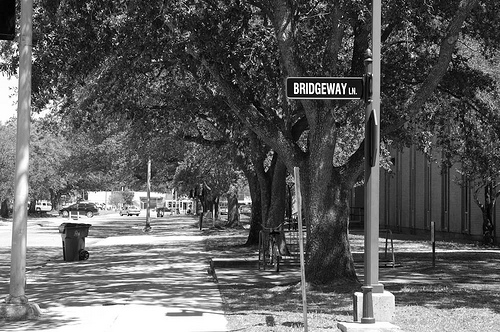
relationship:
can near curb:
[59, 221, 90, 261] [0, 215, 158, 296]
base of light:
[0, 296, 40, 321] [1, 1, 44, 324]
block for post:
[354, 290, 395, 324] [364, 0, 384, 294]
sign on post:
[286, 77, 367, 98] [364, 0, 384, 294]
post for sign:
[364, 0, 384, 294] [286, 77, 367, 98]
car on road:
[119, 204, 140, 217] [1, 215, 158, 305]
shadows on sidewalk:
[0, 213, 233, 331] [1, 214, 233, 331]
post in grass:
[364, 0, 384, 294] [203, 230, 499, 331]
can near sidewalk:
[59, 221, 90, 261] [1, 214, 233, 331]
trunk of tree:
[298, 178, 362, 294] [2, 2, 499, 293]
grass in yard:
[203, 230, 499, 331] [205, 235, 499, 331]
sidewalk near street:
[1, 214, 233, 331] [1, 215, 158, 305]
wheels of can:
[79, 249, 89, 260] [59, 221, 90, 261]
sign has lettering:
[286, 77, 367, 98] [294, 83, 357, 95]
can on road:
[59, 221, 90, 261] [1, 215, 158, 305]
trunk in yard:
[298, 178, 362, 294] [205, 235, 499, 331]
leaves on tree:
[1, 0, 498, 193] [2, 2, 499, 293]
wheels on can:
[79, 249, 89, 260] [59, 221, 90, 261]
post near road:
[364, 0, 384, 294] [1, 215, 158, 305]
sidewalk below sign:
[1, 214, 233, 331] [286, 77, 367, 98]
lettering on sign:
[294, 83, 357, 95] [286, 77, 367, 98]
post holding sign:
[364, 0, 384, 294] [286, 77, 367, 98]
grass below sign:
[203, 230, 499, 331] [286, 77, 367, 98]